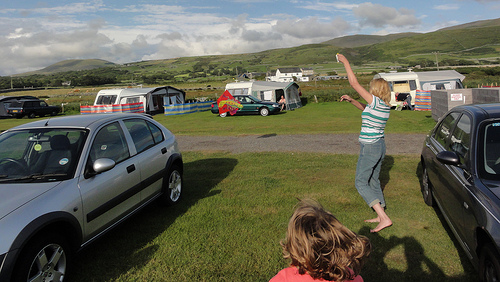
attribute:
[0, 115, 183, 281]
car — silver, grey, parked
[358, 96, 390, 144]
shirt — green, white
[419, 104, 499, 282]
car — black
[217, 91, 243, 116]
kite — multi colored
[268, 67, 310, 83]
house — white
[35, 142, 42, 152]
item — round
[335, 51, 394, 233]
woman — barefoot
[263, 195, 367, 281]
female — sitting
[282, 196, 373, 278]
shiny hair — brown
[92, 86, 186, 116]
tent — large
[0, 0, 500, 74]
sky — blue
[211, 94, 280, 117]
car — green